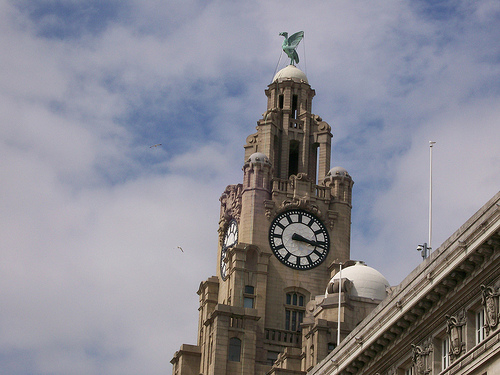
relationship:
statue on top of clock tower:
[280, 30, 305, 68] [171, 82, 352, 373]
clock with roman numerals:
[270, 209, 331, 270] [295, 254, 303, 268]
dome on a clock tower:
[274, 66, 310, 84] [171, 82, 352, 373]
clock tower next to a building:
[171, 82, 352, 373] [303, 262, 400, 369]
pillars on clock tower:
[244, 87, 332, 189] [171, 82, 352, 373]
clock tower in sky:
[171, 82, 352, 373] [2, 4, 498, 374]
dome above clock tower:
[274, 66, 310, 84] [171, 82, 352, 373]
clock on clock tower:
[270, 209, 331, 270] [171, 82, 352, 373]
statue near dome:
[280, 30, 305, 68] [274, 66, 310, 84]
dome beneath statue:
[274, 66, 310, 84] [280, 30, 305, 68]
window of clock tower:
[285, 289, 307, 331] [171, 82, 352, 373]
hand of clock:
[293, 233, 324, 250] [270, 209, 331, 270]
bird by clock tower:
[175, 246, 185, 252] [171, 82, 352, 373]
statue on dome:
[280, 30, 305, 68] [274, 66, 310, 84]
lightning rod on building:
[428, 140, 438, 266] [303, 262, 400, 369]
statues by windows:
[446, 310, 465, 357] [474, 308, 491, 347]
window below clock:
[285, 289, 307, 331] [270, 209, 331, 270]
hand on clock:
[293, 233, 324, 250] [270, 209, 331, 270]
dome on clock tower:
[274, 66, 310, 84] [171, 82, 352, 373]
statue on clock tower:
[280, 30, 305, 68] [171, 82, 352, 373]